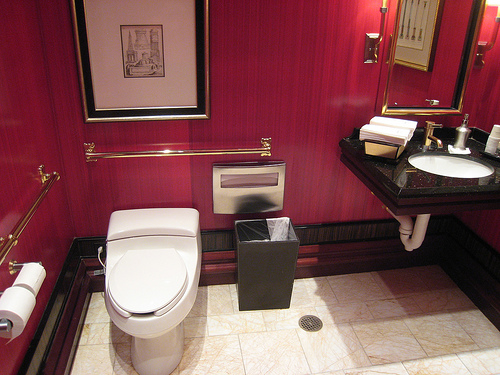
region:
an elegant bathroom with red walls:
[11, 4, 483, 365]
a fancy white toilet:
[89, 205, 214, 374]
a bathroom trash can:
[231, 214, 305, 314]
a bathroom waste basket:
[228, 213, 304, 320]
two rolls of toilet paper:
[3, 254, 48, 351]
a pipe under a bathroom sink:
[381, 203, 434, 253]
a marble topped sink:
[342, 107, 498, 214]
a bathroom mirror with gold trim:
[382, 0, 483, 113]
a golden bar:
[78, 137, 280, 167]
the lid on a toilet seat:
[108, 252, 188, 312]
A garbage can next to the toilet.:
[228, 219, 325, 313]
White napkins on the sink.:
[351, 105, 423, 163]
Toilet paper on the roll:
[1, 249, 44, 299]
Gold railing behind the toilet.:
[76, 143, 285, 176]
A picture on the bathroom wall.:
[65, 12, 225, 122]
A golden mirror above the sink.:
[377, 4, 473, 126]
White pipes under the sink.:
[376, 215, 433, 250]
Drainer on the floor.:
[290, 306, 325, 338]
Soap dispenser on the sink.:
[446, 115, 475, 154]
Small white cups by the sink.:
[465, 118, 499, 159]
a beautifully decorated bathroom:
[3, 2, 490, 369]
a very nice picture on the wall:
[53, 0, 235, 127]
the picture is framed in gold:
[60, 7, 240, 128]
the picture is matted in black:
[53, 3, 235, 126]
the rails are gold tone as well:
[76, 135, 311, 162]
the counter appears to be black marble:
[352, 149, 492, 217]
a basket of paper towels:
[368, 110, 418, 167]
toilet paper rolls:
[6, 247, 58, 331]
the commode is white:
[92, 193, 212, 373]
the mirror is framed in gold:
[352, 11, 493, 117]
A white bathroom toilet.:
[102, 206, 197, 373]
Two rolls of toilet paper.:
[0, 261, 60, 339]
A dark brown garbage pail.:
[233, 215, 295, 310]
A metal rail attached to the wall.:
[76, 137, 281, 162]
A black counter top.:
[335, 116, 495, 206]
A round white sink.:
[405, 150, 490, 175]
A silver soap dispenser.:
[450, 110, 470, 150]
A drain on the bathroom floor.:
[292, 312, 327, 333]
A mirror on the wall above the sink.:
[375, 0, 485, 115]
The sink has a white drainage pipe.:
[387, 206, 427, 249]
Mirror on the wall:
[376, 1, 485, 116]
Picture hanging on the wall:
[68, 0, 210, 122]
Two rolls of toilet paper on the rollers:
[2, 262, 47, 345]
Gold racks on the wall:
[2, 138, 272, 267]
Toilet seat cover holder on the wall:
[211, 161, 286, 214]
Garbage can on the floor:
[233, 215, 298, 312]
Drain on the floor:
[298, 313, 325, 333]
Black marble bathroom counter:
[340, 129, 499, 215]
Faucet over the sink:
[423, 119, 445, 149]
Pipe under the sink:
[382, 207, 431, 252]